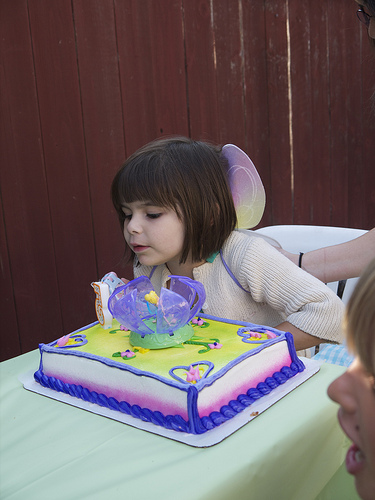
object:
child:
[110, 134, 346, 357]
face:
[123, 198, 183, 265]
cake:
[34, 270, 306, 437]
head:
[118, 135, 238, 266]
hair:
[110, 134, 238, 269]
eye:
[146, 213, 164, 219]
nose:
[127, 216, 143, 235]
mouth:
[130, 243, 151, 255]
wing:
[113, 288, 156, 333]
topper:
[107, 274, 206, 336]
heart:
[170, 360, 214, 384]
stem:
[184, 339, 223, 354]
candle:
[90, 281, 112, 327]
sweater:
[133, 228, 346, 356]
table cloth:
[1, 347, 354, 499]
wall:
[1, 4, 375, 366]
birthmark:
[355, 425, 360, 430]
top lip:
[345, 445, 365, 474]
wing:
[222, 143, 266, 231]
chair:
[250, 224, 366, 359]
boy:
[326, 259, 374, 499]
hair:
[342, 258, 374, 378]